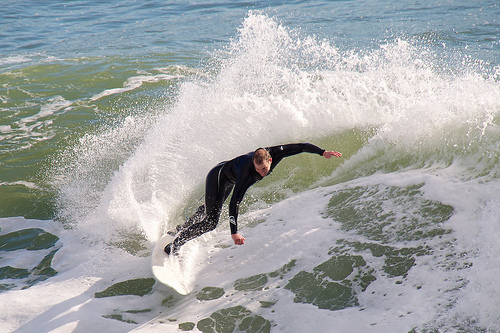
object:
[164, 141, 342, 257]
man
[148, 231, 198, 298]
surfboard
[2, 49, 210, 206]
waves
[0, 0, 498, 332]
water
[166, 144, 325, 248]
wet suit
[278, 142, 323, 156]
arm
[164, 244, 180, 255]
feet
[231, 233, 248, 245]
hand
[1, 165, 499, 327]
foam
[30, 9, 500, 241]
spray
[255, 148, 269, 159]
bald spot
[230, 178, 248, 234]
arm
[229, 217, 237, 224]
writing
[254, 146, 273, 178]
head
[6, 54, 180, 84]
crest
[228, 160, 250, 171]
back